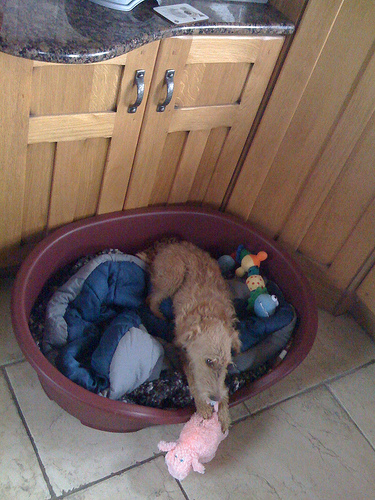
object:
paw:
[196, 399, 215, 420]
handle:
[127, 69, 146, 114]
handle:
[156, 69, 175, 113]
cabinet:
[0, 35, 287, 269]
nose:
[208, 394, 219, 402]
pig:
[157, 400, 229, 480]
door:
[123, 33, 286, 214]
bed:
[42, 254, 298, 402]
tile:
[326, 360, 375, 452]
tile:
[243, 308, 375, 416]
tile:
[177, 384, 375, 500]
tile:
[59, 451, 189, 500]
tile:
[4, 355, 249, 498]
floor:
[0, 274, 375, 500]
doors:
[22, 38, 161, 246]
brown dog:
[144, 235, 243, 433]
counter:
[0, 0, 297, 64]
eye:
[206, 358, 214, 366]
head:
[177, 320, 243, 403]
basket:
[10, 203, 320, 433]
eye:
[178, 457, 184, 462]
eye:
[174, 454, 178, 459]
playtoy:
[234, 250, 279, 320]